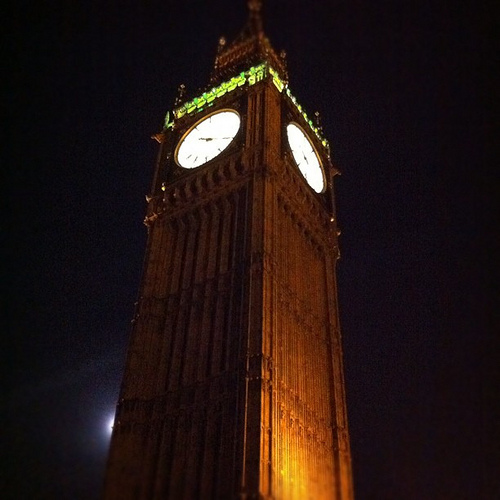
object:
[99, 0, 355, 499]
tower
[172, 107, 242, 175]
clock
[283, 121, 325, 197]
clock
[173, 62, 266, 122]
lights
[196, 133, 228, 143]
hands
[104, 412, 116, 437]
moon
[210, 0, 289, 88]
tip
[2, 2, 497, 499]
sky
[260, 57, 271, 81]
corner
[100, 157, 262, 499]
wall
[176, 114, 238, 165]
numbers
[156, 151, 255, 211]
carvings